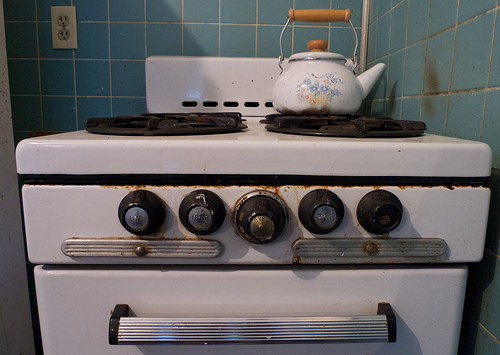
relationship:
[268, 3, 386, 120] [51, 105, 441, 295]
kettle on stove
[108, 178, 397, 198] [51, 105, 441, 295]
rust stains on stove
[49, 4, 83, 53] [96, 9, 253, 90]
outlet on wall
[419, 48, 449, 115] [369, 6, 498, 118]
burn stain on tiles